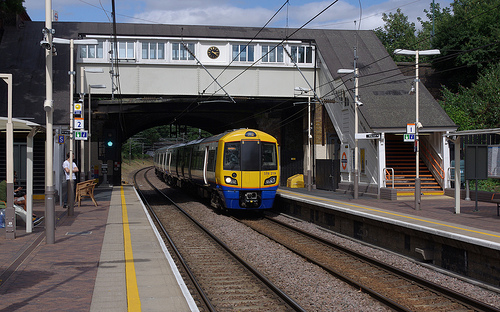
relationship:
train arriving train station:
[150, 122, 286, 211] [0, 0, 499, 311]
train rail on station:
[241, 216, 496, 310] [18, 8, 478, 310]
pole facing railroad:
[324, 44, 438, 217] [157, 124, 455, 310]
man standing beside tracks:
[59, 149, 80, 214] [162, 196, 494, 310]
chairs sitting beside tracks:
[72, 167, 99, 214] [135, 162, 498, 311]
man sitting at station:
[59, 150, 80, 209] [2, 4, 496, 302]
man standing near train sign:
[59, 150, 80, 209] [75, 110, 94, 160]